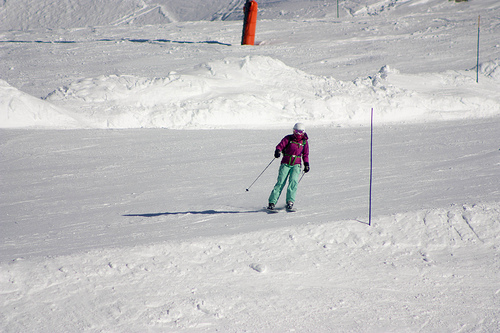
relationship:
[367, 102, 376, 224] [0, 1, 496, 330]
pole in snow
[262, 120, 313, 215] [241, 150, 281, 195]
person holding ski pole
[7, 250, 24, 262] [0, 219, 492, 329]
clump on slope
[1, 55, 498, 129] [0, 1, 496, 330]
clump on snow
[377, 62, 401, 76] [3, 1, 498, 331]
clump on slope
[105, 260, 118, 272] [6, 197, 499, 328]
clump on slope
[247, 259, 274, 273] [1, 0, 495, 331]
clump on ski slope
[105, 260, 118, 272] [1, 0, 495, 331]
clump on ski slope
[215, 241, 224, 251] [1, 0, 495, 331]
clump on ski slope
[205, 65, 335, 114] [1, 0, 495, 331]
clump on ski slope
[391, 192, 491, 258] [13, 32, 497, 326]
clump on slope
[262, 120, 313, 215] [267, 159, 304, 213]
person wearing pants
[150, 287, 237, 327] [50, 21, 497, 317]
snow on hill side